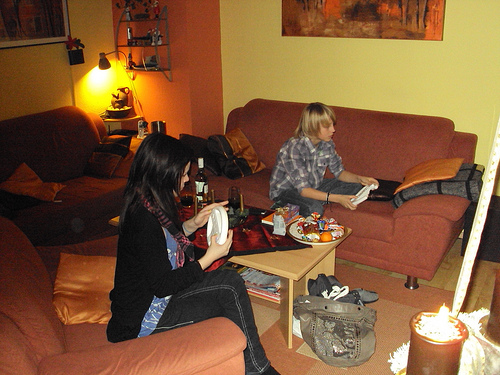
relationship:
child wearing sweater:
[109, 132, 285, 375] [103, 193, 206, 342]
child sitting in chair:
[109, 132, 285, 375] [1, 207, 249, 371]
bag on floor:
[289, 288, 379, 368] [233, 233, 498, 373]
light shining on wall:
[64, 55, 141, 95] [1, 0, 221, 135]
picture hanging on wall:
[278, 0, 449, 42] [68, 0, 498, 163]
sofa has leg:
[186, 93, 479, 293] [396, 270, 431, 299]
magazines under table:
[238, 272, 280, 303] [206, 192, 345, 362]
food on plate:
[298, 210, 345, 241] [288, 216, 351, 246]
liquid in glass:
[227, 197, 243, 209] [227, 184, 240, 211]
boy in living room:
[268, 100, 381, 221] [2, 0, 499, 372]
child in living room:
[109, 132, 280, 372] [2, 0, 499, 372]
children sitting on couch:
[105, 101, 378, 373] [185, 95, 477, 290]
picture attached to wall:
[278, 0, 449, 42] [218, 0, 498, 194]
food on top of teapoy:
[295, 211, 347, 244] [281, 210, 350, 246]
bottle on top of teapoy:
[190, 157, 210, 214] [186, 187, 255, 220]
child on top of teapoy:
[109, 132, 285, 375] [186, 187, 255, 220]